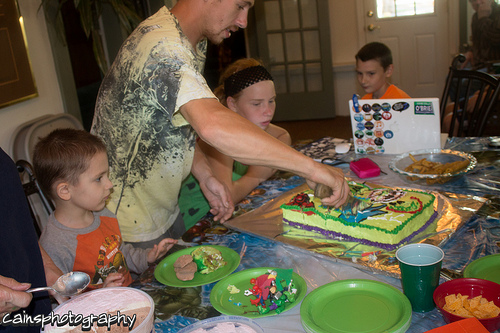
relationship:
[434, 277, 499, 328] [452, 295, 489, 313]
bowl has chips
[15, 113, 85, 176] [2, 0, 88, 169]
chair on wall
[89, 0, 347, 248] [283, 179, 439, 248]
man cutting cake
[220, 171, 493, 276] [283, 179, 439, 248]
tinfoil under cake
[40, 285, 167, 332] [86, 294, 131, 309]
tub has ice cream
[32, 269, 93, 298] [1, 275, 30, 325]
spoon in hand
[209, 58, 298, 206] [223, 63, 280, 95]
girl wearing headband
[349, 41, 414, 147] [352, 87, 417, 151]
boy wearing shirt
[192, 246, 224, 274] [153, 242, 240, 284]
cake on plate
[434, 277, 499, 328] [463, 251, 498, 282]
bowl next to plate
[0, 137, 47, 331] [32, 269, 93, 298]
person holding spoon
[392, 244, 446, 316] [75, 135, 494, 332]
cup on table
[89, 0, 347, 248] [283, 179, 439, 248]
man slicing cake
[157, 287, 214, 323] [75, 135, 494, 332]
hulk on table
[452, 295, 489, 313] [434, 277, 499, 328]
chips in bowl